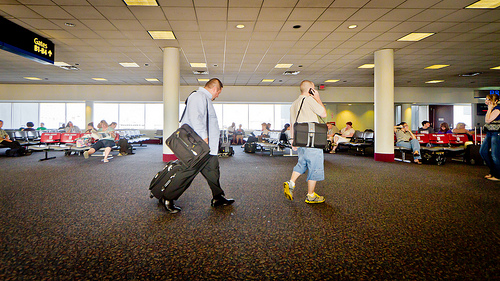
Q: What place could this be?
A: It is an airport.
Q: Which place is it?
A: It is an airport.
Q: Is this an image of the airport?
A: Yes, it is showing the airport.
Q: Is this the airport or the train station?
A: It is the airport.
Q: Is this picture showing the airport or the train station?
A: It is showing the airport.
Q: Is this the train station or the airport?
A: It is the airport.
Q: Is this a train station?
A: No, it is an airport.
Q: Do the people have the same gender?
A: No, they are both male and female.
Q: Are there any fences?
A: No, there are no fences.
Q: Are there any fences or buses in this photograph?
A: No, there are no fences or buses.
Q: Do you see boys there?
A: No, there are no boys.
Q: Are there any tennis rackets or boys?
A: No, there are no boys or tennis rackets.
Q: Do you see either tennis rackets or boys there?
A: No, there are no boys or tennis rackets.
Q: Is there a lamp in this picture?
A: No, there are no lamps.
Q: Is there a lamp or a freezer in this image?
A: No, there are no lamps or refrigerators.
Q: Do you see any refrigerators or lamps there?
A: No, there are no lamps or refrigerators.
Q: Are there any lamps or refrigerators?
A: No, there are no lamps or refrigerators.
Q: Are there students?
A: No, there are no students.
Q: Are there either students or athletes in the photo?
A: No, there are no students or athletes.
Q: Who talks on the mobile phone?
A: The man talks on the mobile phone.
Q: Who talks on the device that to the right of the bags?
A: The man talks on the mobile phone.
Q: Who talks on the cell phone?
A: The man talks on the mobile phone.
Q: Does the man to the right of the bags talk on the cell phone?
A: Yes, the man talks on the cell phone.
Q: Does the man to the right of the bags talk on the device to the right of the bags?
A: Yes, the man talks on the cell phone.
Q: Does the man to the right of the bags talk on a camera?
A: No, the man talks on the cell phone.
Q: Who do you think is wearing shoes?
A: The man is wearing shoes.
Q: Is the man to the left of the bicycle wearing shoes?
A: Yes, the man is wearing shoes.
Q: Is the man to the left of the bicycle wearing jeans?
A: No, the man is wearing shoes.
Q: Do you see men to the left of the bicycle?
A: Yes, there is a man to the left of the bicycle.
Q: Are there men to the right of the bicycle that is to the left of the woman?
A: No, the man is to the left of the bicycle.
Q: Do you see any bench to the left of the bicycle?
A: No, there is a man to the left of the bicycle.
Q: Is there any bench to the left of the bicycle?
A: No, there is a man to the left of the bicycle.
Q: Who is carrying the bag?
A: The man is carrying the bag.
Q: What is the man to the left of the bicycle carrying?
A: The man is carrying a bag.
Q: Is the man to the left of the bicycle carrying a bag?
A: Yes, the man is carrying a bag.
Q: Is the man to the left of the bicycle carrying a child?
A: No, the man is carrying a bag.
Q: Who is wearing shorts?
A: The man is wearing shorts.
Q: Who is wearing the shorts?
A: The man is wearing shorts.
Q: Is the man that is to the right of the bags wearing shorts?
A: Yes, the man is wearing shorts.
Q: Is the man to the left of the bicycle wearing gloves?
A: No, the man is wearing shorts.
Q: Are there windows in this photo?
A: Yes, there are windows.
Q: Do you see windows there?
A: Yes, there are windows.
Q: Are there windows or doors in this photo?
A: Yes, there are windows.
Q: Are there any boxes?
A: No, there are no boxes.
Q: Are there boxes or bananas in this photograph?
A: No, there are no boxes or bananas.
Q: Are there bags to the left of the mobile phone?
A: Yes, there are bags to the left of the mobile phone.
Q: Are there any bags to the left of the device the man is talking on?
A: Yes, there are bags to the left of the mobile phone.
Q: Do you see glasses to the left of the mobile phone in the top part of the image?
A: No, there are bags to the left of the cellphone.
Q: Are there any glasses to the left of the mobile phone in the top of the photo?
A: No, there are bags to the left of the cellphone.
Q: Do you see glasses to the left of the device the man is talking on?
A: No, there are bags to the left of the cellphone.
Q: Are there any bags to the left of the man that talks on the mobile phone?
A: Yes, there are bags to the left of the man.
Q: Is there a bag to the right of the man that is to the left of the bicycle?
A: No, the bags are to the left of the man.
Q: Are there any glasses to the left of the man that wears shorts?
A: No, there are bags to the left of the man.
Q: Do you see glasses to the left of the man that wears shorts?
A: No, there are bags to the left of the man.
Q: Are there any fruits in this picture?
A: No, there are no fruits.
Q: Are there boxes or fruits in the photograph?
A: No, there are no fruits or boxes.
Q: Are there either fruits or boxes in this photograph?
A: No, there are no fruits or boxes.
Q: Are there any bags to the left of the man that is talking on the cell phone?
A: Yes, there are bags to the left of the man.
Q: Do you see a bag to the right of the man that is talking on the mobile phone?
A: No, the bags are to the left of the man.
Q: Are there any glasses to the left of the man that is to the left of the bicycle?
A: No, there are bags to the left of the man.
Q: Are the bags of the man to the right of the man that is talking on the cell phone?
A: No, the bags are to the left of the man.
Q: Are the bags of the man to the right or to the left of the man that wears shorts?
A: The bags are to the left of the man.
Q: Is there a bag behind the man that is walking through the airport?
A: Yes, there are bags behind the man.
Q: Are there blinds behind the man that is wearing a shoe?
A: No, there are bags behind the man.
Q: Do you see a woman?
A: Yes, there is a woman.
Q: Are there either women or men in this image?
A: Yes, there is a woman.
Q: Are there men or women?
A: Yes, there is a woman.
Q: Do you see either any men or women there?
A: Yes, there is a woman.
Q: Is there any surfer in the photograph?
A: No, there are no surfers.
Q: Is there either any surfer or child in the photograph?
A: No, there are no surfers or children.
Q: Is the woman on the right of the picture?
A: Yes, the woman is on the right of the image.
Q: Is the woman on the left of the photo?
A: No, the woman is on the right of the image.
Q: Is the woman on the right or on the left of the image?
A: The woman is on the right of the image.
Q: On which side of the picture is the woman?
A: The woman is on the right of the image.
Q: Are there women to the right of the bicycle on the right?
A: Yes, there is a woman to the right of the bicycle.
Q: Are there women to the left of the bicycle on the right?
A: No, the woman is to the right of the bicycle.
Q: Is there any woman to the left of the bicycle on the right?
A: No, the woman is to the right of the bicycle.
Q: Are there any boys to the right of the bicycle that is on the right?
A: No, there is a woman to the right of the bicycle.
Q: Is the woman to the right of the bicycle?
A: Yes, the woman is to the right of the bicycle.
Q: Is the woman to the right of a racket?
A: No, the woman is to the right of the bicycle.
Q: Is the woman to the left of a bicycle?
A: No, the woman is to the right of a bicycle.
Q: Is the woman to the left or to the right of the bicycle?
A: The woman is to the right of the bicycle.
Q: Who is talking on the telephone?
A: The woman is talking on the telephone.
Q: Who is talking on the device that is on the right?
A: The woman is talking on the telephone.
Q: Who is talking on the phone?
A: The woman is talking on the telephone.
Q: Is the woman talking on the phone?
A: Yes, the woman is talking on the phone.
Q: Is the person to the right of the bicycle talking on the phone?
A: Yes, the woman is talking on the phone.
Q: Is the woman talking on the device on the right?
A: Yes, the woman is talking on the phone.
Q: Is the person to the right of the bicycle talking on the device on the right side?
A: Yes, the woman is talking on the phone.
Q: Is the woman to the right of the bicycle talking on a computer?
A: No, the woman is talking on the phone.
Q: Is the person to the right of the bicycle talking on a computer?
A: No, the woman is talking on the phone.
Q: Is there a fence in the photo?
A: No, there are no fences.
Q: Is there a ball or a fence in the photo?
A: No, there are no fences or balls.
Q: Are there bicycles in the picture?
A: Yes, there is a bicycle.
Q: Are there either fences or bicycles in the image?
A: Yes, there is a bicycle.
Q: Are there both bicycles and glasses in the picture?
A: No, there is a bicycle but no glasses.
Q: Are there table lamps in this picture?
A: No, there are no table lamps.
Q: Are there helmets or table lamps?
A: No, there are no table lamps or helmets.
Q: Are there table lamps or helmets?
A: No, there are no table lamps or helmets.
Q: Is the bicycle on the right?
A: Yes, the bicycle is on the right of the image.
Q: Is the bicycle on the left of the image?
A: No, the bicycle is on the right of the image.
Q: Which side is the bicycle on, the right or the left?
A: The bicycle is on the right of the image.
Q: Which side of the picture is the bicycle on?
A: The bicycle is on the right of the image.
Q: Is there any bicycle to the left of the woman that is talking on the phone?
A: Yes, there is a bicycle to the left of the woman.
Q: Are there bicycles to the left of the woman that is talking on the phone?
A: Yes, there is a bicycle to the left of the woman.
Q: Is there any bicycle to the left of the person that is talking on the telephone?
A: Yes, there is a bicycle to the left of the woman.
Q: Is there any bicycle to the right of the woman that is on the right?
A: No, the bicycle is to the left of the woman.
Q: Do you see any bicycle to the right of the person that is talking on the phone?
A: No, the bicycle is to the left of the woman.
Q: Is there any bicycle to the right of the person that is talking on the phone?
A: No, the bicycle is to the left of the woman.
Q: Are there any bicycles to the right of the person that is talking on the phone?
A: No, the bicycle is to the left of the woman.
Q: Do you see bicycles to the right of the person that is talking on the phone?
A: No, the bicycle is to the left of the woman.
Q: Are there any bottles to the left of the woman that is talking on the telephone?
A: No, there is a bicycle to the left of the woman.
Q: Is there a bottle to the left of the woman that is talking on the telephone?
A: No, there is a bicycle to the left of the woman.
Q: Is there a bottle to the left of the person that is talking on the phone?
A: No, there is a bicycle to the left of the woman.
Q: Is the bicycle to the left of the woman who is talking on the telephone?
A: Yes, the bicycle is to the left of the woman.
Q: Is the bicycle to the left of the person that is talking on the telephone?
A: Yes, the bicycle is to the left of the woman.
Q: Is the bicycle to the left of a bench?
A: No, the bicycle is to the left of the woman.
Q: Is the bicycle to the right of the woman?
A: No, the bicycle is to the left of the woman.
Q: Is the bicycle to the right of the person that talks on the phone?
A: No, the bicycle is to the left of the woman.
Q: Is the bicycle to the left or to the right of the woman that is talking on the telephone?
A: The bicycle is to the left of the woman.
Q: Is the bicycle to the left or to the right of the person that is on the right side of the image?
A: The bicycle is to the left of the woman.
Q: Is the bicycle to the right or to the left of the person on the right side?
A: The bicycle is to the left of the woman.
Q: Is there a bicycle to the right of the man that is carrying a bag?
A: Yes, there is a bicycle to the right of the man.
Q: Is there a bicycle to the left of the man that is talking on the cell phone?
A: No, the bicycle is to the right of the man.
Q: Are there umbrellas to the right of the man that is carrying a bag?
A: No, there is a bicycle to the right of the man.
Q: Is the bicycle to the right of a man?
A: Yes, the bicycle is to the right of a man.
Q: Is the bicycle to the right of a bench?
A: No, the bicycle is to the right of a man.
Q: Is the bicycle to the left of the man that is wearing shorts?
A: No, the bicycle is to the right of the man.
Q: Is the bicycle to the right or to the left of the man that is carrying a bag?
A: The bicycle is to the right of the man.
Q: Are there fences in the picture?
A: No, there are no fences.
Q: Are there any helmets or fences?
A: No, there are no fences or helmets.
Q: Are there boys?
A: No, there are no boys.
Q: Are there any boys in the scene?
A: No, there are no boys.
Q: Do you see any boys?
A: No, there are no boys.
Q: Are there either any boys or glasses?
A: No, there are no boys or glasses.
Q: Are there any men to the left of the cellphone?
A: Yes, there is a man to the left of the cellphone.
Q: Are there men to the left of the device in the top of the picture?
A: Yes, there is a man to the left of the cellphone.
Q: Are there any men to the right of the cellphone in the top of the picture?
A: No, the man is to the left of the cellphone.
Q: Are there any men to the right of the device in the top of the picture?
A: No, the man is to the left of the cellphone.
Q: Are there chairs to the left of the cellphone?
A: No, there is a man to the left of the cellphone.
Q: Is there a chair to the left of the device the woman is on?
A: No, there is a man to the left of the cellphone.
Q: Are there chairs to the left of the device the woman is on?
A: No, there is a man to the left of the cellphone.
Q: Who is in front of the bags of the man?
A: The man is in front of the bags.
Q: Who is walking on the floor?
A: The man is walking on the floor.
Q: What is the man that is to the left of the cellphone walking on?
A: The man is walking on the floor.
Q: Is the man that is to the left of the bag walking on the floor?
A: Yes, the man is walking on the floor.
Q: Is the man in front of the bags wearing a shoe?
A: Yes, the man is wearing a shoe.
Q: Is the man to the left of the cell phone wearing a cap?
A: No, the man is wearing a shoe.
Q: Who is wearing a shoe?
A: The man is wearing a shoe.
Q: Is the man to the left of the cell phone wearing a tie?
A: No, the man is wearing a shoe.